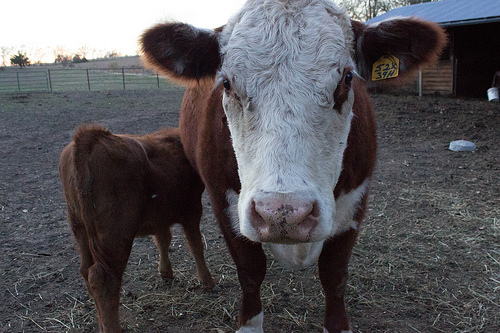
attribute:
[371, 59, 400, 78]
tag — yellow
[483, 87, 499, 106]
bucket — white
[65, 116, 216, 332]
calf — baby, small, brown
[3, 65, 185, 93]
fence — metal, black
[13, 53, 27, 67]
tree — large, growing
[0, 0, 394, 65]
sky — clear, white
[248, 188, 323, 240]
nose — pink, spotted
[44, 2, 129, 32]
sky — cloudy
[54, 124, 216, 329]
calf — her's, brown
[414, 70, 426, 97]
post — Wooden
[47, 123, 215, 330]
animal — smaller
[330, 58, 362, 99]
eye — brown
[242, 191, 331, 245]
nose — big, pinkish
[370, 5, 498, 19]
roof — black 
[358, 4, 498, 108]
building — wooden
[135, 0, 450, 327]
cow — mother, staring, white, brown, adult cow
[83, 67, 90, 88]
fence post — Third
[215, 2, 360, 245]
cow's face — curry , white face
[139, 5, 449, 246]
head — white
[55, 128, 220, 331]
cow — baby cow, brown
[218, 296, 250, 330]
hoof — small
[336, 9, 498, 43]
roof — black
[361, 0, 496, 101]
barn — wood, metal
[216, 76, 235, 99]
eye — cow's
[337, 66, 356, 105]
eye — cow's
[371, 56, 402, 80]
tag — written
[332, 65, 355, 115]
ring — Brown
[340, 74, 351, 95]
eye — cow's